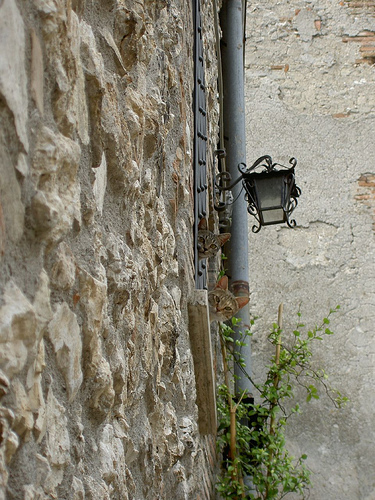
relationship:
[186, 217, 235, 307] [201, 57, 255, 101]
cats looking out window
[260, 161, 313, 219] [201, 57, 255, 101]
lamp next to window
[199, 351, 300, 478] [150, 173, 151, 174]
plant next to building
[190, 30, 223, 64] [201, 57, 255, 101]
sill on window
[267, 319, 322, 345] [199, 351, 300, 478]
leaves on plant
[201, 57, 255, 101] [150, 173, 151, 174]
window on building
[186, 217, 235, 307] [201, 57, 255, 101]
cats in window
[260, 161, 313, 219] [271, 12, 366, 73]
lamp attached to wall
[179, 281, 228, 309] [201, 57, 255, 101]
ledge on window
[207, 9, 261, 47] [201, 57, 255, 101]
bars on window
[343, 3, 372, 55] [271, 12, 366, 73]
bricks on wall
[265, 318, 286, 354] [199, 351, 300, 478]
leaf on plant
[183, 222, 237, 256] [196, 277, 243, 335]
head of cat